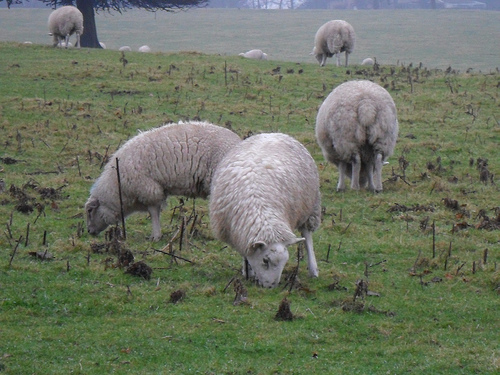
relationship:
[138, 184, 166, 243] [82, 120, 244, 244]
leg on sheep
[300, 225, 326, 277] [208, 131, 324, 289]
leg on sheep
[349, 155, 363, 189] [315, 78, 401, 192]
leg on sheep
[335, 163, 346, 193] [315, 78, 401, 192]
leg on sheep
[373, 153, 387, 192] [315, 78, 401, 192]
leg on sheep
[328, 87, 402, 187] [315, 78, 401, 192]
back of sheep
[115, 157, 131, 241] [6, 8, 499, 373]
stem on ground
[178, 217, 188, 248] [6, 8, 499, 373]
stem on ground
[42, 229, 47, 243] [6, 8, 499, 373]
stem on ground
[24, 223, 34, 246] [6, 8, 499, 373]
stem on ground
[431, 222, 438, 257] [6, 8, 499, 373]
stem on ground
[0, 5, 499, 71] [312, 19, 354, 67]
lower elevation behind sheep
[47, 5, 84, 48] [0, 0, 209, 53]
sheep under tree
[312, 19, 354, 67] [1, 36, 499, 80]
sheep near edge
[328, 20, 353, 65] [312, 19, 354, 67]
backside of sheep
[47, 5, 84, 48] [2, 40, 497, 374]
sheep eating grass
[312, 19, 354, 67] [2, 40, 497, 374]
sheep eating grass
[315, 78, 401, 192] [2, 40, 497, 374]
sheep eating grass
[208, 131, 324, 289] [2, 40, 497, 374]
sheep eating grass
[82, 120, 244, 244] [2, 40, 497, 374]
sheep eating grass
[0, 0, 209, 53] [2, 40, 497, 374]
tree on grass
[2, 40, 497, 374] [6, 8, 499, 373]
grass in field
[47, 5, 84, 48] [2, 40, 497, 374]
sheep on grass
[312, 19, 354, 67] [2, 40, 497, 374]
sheep on grass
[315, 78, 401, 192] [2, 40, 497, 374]
sheep on grass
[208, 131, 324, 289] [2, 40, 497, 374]
sheep on grass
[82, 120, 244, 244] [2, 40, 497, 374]
sheep on grass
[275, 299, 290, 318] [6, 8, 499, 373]
plant on ground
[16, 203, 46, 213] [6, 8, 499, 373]
plant on ground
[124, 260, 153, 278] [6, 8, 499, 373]
plant on ground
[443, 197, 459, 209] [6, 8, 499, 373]
plant on ground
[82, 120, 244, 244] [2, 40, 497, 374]
sheep grazing grass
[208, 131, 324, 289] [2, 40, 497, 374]
sheep grazing grass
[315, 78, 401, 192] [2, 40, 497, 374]
sheep grazing grass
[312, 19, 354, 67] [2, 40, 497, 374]
sheep grazing grass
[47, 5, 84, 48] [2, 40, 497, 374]
sheep grazing grass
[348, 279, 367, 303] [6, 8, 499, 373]
plant on ground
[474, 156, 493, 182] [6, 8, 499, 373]
plant on ground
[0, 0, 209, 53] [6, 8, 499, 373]
tree on ground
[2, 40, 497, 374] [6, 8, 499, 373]
grass on ground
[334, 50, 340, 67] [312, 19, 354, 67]
leg of sheep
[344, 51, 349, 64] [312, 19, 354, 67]
leg of sheep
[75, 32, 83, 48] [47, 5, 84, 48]
leg of sheep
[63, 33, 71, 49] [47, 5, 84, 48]
leg of sheep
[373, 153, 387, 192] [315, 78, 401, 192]
leg of sheep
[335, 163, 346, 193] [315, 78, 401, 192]
leg of sheep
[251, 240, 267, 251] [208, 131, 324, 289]
ear of sheep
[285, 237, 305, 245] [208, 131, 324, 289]
ear of sheep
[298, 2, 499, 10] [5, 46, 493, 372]
hill beyond field